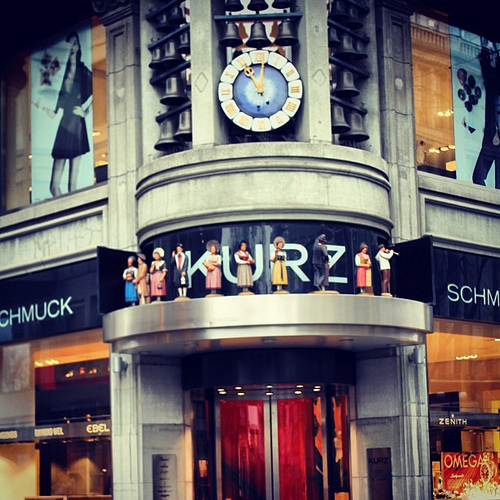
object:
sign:
[447, 283, 500, 310]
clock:
[215, 49, 304, 132]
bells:
[159, 75, 190, 106]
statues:
[310, 233, 330, 290]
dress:
[50, 58, 92, 161]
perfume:
[440, 451, 499, 492]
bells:
[152, 118, 187, 152]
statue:
[147, 245, 167, 300]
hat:
[152, 247, 165, 258]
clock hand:
[237, 59, 263, 95]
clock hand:
[253, 51, 265, 94]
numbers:
[218, 81, 230, 97]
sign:
[0, 294, 73, 329]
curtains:
[218, 385, 313, 500]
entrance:
[212, 379, 328, 499]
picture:
[23, 32, 103, 204]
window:
[5, 25, 109, 211]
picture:
[0, 214, 500, 500]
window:
[31, 329, 112, 500]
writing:
[58, 296, 74, 317]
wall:
[0, 348, 36, 500]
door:
[215, 389, 347, 500]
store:
[0, 18, 499, 500]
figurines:
[171, 243, 189, 297]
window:
[424, 315, 500, 493]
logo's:
[0, 296, 73, 327]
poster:
[439, 451, 500, 493]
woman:
[451, 420, 481, 458]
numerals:
[281, 99, 300, 113]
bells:
[244, 19, 271, 49]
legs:
[68, 154, 83, 193]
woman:
[30, 33, 92, 200]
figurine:
[313, 234, 332, 292]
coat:
[312, 243, 329, 288]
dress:
[270, 248, 288, 285]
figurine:
[268, 235, 290, 291]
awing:
[120, 235, 399, 307]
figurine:
[122, 256, 137, 305]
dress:
[123, 265, 138, 303]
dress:
[234, 250, 255, 289]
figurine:
[234, 241, 255, 293]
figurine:
[132, 254, 150, 304]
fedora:
[136, 253, 146, 262]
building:
[0, 0, 500, 500]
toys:
[217, 20, 243, 49]